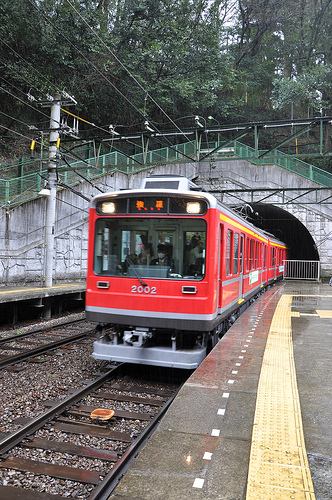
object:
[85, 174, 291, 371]
subway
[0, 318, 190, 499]
track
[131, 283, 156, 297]
number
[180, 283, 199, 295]
headlight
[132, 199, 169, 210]
sign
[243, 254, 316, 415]
line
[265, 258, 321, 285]
fence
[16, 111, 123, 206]
stiar case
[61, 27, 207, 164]
wire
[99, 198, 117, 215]
light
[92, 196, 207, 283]
windhield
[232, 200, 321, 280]
tunnel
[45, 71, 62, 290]
pole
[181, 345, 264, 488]
lines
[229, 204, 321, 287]
gate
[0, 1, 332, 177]
tree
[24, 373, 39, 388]
rock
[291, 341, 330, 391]
water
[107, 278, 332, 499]
road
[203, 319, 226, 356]
wheel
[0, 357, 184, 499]
rail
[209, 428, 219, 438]
square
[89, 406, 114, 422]
square